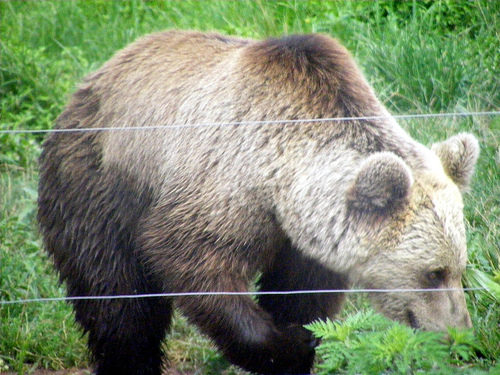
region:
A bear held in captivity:
[32, 25, 475, 365]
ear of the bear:
[353, 160, 403, 226]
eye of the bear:
[423, 255, 447, 290]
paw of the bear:
[220, 309, 305, 367]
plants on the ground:
[335, 328, 414, 364]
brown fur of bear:
[136, 181, 265, 275]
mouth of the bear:
[407, 299, 421, 323]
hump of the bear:
[273, 29, 365, 106]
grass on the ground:
[384, 37, 464, 115]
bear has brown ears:
[305, 144, 465, 226]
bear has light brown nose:
[424, 282, 479, 358]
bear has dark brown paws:
[192, 239, 332, 372]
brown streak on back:
[224, 44, 372, 134]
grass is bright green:
[4, 12, 111, 147]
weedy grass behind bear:
[1, 16, 101, 162]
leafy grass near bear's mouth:
[315, 316, 441, 371]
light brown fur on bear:
[82, 50, 217, 180]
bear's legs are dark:
[81, 134, 168, 374]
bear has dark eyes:
[420, 252, 455, 299]